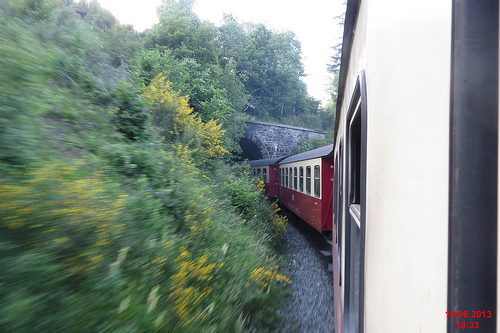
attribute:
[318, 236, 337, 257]
step — metal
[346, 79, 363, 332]
window — open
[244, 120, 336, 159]
bridge — brick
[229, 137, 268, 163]
tunnel — dark, looming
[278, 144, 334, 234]
train car — red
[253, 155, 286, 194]
train car — red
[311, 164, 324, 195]
window — trimmed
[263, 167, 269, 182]
window — trimmed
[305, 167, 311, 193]
window — trimmed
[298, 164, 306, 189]
window — trimmed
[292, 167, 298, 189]
window — trimmed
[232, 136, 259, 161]
tunnel — dark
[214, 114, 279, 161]
tunnel — brick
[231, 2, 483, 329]
train — white, gray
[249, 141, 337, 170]
roof — black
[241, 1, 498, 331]
train — speeding, red, white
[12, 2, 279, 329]
bushes — green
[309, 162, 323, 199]
window — white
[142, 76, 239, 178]
flowers — yellow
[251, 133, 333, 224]
train — red, white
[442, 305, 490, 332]
stamp — time, date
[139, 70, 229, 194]
flowers — yellow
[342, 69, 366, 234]
train window — open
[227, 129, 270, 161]
arch — stone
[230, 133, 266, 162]
tunnel — stone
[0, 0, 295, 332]
bushes — green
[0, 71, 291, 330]
flowers — yellow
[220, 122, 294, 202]
tunnel — brick